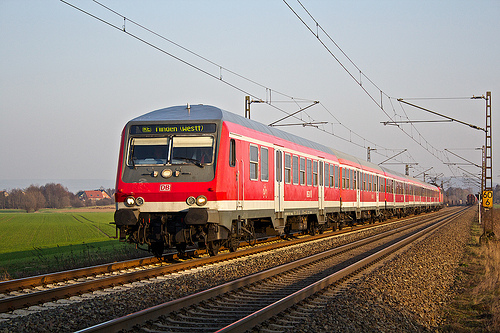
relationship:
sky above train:
[2, 2, 499, 149] [106, 97, 462, 254]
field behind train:
[2, 206, 141, 275] [106, 97, 462, 254]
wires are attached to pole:
[55, 1, 484, 161] [468, 92, 498, 233]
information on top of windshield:
[127, 121, 217, 134] [131, 135, 213, 167]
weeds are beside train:
[0, 245, 142, 272] [106, 97, 462, 254]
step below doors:
[273, 216, 289, 235] [271, 148, 291, 216]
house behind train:
[69, 182, 111, 213] [106, 97, 462, 254]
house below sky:
[69, 182, 111, 213] [2, 2, 499, 149]